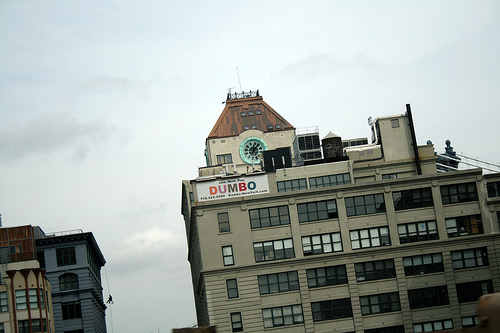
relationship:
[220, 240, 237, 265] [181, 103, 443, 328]
window on building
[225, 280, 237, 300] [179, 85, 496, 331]
window on building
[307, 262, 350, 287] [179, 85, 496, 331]
window on building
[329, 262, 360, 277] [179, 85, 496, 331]
window on building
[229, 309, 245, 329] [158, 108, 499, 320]
window on building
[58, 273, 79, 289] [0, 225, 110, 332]
window on building